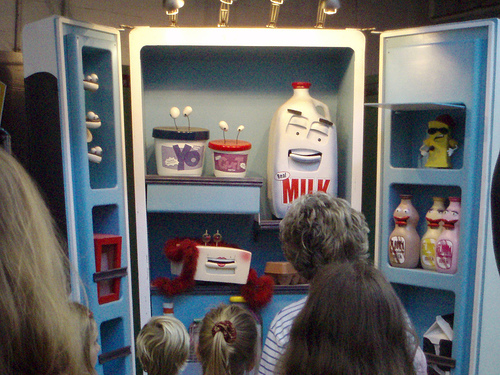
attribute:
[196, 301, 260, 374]
hair — blonde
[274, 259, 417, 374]
hair — brown, long, grey, black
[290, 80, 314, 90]
top — red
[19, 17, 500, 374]
refrigerator — blue, fake, illuminated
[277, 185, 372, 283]
hair — short, blonde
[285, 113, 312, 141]
eye — white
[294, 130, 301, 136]
pupil — black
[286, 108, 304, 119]
eyebrow — black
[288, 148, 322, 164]
mouth — white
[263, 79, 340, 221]
milk carton — giant, cartoonish, white, large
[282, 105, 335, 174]
face — cartoonish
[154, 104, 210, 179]
yogurt container — white, purple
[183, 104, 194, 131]
eye — marshmallow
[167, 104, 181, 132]
eye — marshmallow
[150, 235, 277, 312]
scarf — red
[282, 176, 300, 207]
letter — red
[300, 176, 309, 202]
letter — red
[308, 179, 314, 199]
letter — red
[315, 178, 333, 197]
letter — red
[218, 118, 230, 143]
eyeball — marshmallow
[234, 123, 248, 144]
eyeball — marshmallow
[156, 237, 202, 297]
arm — red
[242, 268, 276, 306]
arm — red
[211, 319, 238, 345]
holder — brown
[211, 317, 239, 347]
hair scrunchie — red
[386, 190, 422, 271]
bottle — brown, chocolate milk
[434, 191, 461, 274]
bottle — pink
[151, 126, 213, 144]
lid — black, grey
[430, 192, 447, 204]
lid — yellow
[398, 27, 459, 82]
light — shining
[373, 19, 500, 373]
door — blue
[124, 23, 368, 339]
edge — white